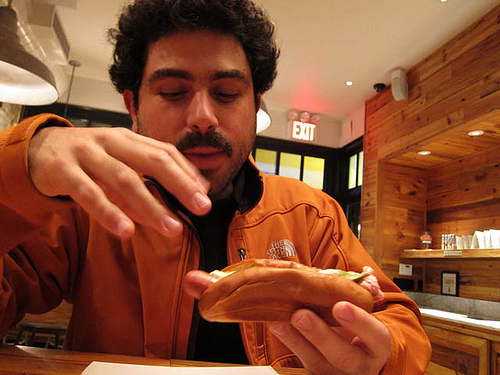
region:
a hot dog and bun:
[181, 257, 385, 322]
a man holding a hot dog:
[1, 0, 434, 373]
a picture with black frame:
[439, 270, 460, 297]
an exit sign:
[288, 116, 317, 144]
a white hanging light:
[1, 0, 61, 105]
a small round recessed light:
[414, 148, 433, 158]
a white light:
[389, 68, 408, 104]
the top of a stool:
[13, 318, 68, 350]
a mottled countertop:
[400, 287, 498, 329]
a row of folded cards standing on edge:
[442, 229, 497, 249]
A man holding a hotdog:
[1, 1, 431, 374]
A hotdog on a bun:
[182, 260, 384, 320]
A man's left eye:
[206, 76, 243, 102]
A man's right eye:
[152, 76, 186, 106]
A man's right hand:
[27, 126, 210, 238]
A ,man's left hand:
[267, 299, 392, 374]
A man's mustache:
[172, 133, 234, 155]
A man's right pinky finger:
[77, 181, 132, 238]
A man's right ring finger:
[86, 147, 183, 238]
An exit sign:
[282, 113, 318, 141]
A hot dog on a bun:
[179, 256, 386, 326]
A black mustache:
[166, 130, 236, 158]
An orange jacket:
[0, 114, 431, 374]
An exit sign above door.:
[290, 116, 318, 140]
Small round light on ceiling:
[346, 79, 355, 87]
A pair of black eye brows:
[140, 65, 256, 85]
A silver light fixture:
[0, 0, 59, 105]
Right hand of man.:
[27, 126, 212, 239]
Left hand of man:
[268, 302, 391, 374]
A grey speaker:
[391, 69, 408, 101]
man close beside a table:
[0, 0, 450, 372]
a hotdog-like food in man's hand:
[178, 253, 393, 373]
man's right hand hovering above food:
[28, 113, 380, 326]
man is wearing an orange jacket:
[2, 112, 431, 374]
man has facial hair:
[166, 125, 249, 189]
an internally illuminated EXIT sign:
[287, 117, 318, 143]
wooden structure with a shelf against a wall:
[363, 7, 498, 374]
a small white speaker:
[386, 57, 409, 105]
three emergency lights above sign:
[283, 108, 325, 145]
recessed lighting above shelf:
[400, 118, 497, 257]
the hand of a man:
[29, 117, 213, 242]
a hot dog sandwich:
[175, 258, 385, 326]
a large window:
[301, 158, 320, 190]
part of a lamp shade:
[0, 8, 60, 110]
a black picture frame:
[437, 270, 463, 292]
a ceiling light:
[465, 128, 485, 138]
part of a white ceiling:
[72, 73, 126, 113]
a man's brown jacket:
[1, 110, 438, 372]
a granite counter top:
[405, 289, 499, 334]